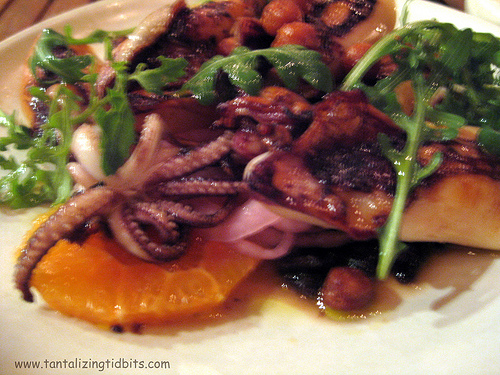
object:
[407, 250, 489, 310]
frog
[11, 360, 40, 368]
ws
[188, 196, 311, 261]
onion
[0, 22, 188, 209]
vegetable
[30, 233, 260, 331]
orange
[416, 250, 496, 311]
sauce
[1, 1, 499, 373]
plate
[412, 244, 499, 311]
shadow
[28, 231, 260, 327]
hot dogs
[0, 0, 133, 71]
table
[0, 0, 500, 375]
clock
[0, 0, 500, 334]
food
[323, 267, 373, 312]
berry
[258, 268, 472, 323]
juice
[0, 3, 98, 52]
edge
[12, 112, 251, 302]
calamari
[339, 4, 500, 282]
green stem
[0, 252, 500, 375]
background